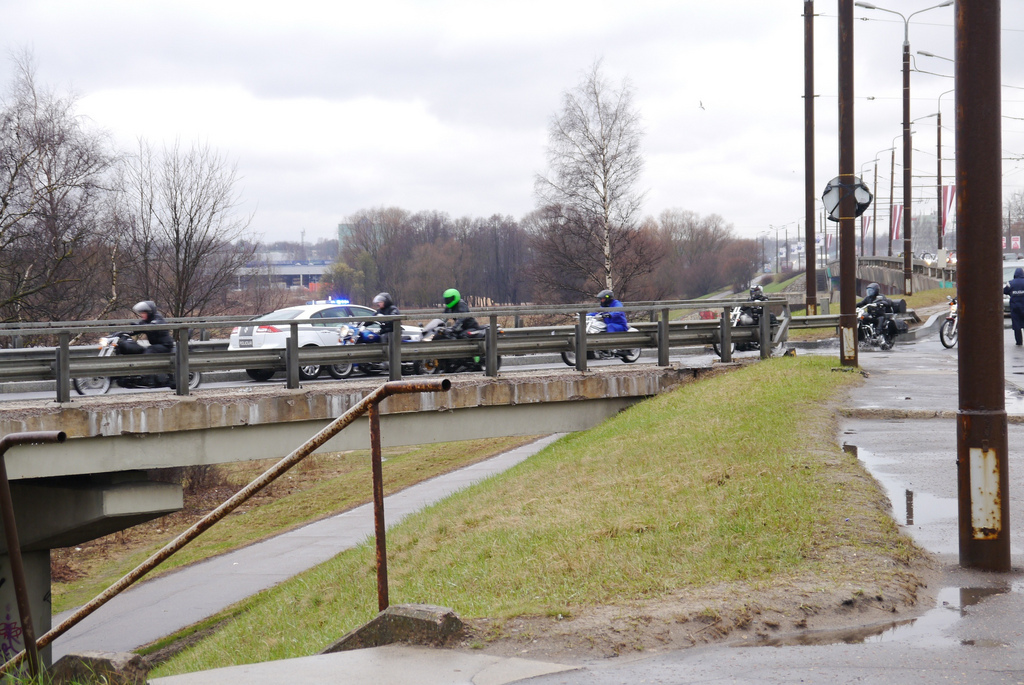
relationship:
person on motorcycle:
[740, 283, 768, 319] [708, 285, 779, 365]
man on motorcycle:
[112, 301, 173, 353] [72, 338, 204, 397]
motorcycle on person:
[328, 315, 421, 380] [357, 289, 407, 348]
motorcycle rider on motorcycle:
[443, 288, 481, 339] [428, 286, 491, 347]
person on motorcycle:
[862, 286, 888, 319] [845, 283, 915, 344]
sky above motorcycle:
[4, 2, 1023, 293] [328, 315, 421, 380]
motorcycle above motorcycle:
[328, 315, 421, 380] [415, 322, 502, 367]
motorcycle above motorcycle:
[328, 315, 421, 380] [855, 306, 906, 358]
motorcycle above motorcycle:
[328, 315, 421, 380] [706, 309, 792, 358]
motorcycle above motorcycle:
[328, 315, 421, 380] [558, 325, 654, 365]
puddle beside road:
[852, 447, 964, 547] [849, 264, 1020, 547]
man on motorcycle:
[112, 301, 173, 353] [65, 304, 198, 410]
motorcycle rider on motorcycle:
[443, 288, 481, 339] [400, 288, 502, 374]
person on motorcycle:
[945, 281, 971, 297] [939, 305, 965, 351]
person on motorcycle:
[592, 278, 632, 343] [570, 319, 665, 367]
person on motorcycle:
[747, 278, 774, 324] [719, 307, 796, 366]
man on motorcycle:
[362, 292, 405, 335] [321, 313, 413, 365]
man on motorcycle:
[112, 301, 173, 353] [86, 335, 207, 392]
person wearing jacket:
[586, 289, 629, 332] [595, 302, 640, 348]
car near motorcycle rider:
[220, 287, 439, 368] [437, 284, 488, 349]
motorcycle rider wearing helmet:
[437, 284, 488, 349] [437, 284, 463, 313]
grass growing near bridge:
[143, 364, 875, 682] [5, 298, 792, 656]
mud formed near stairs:
[487, 582, 928, 641] [47, 603, 458, 681]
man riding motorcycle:
[111, 302, 173, 354] [77, 331, 201, 398]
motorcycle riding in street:
[77, 331, 201, 398] [2, 331, 848, 423]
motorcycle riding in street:
[326, 307, 419, 380] [1, 307, 861, 441]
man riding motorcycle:
[359, 284, 401, 329] [326, 307, 419, 380]